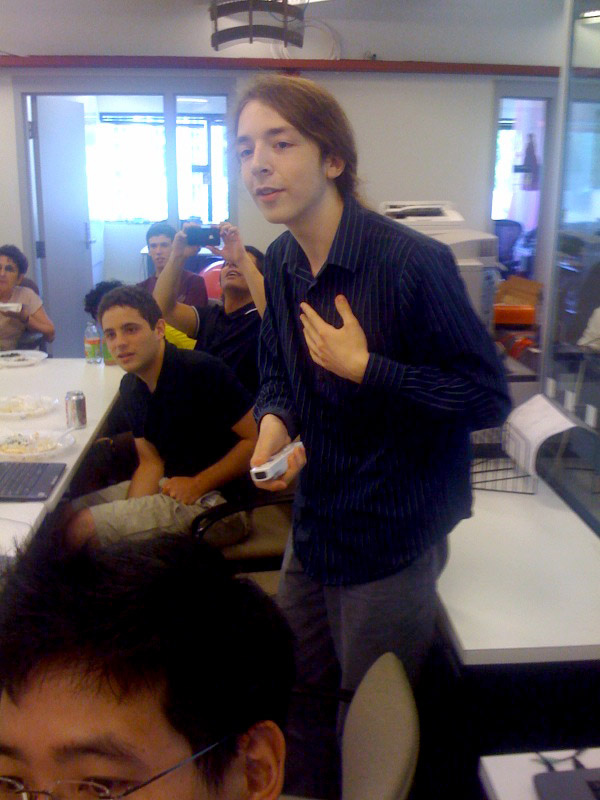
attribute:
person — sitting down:
[120, 205, 215, 328]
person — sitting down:
[5, 528, 305, 794]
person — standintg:
[207, 85, 497, 749]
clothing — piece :
[93, 352, 249, 503]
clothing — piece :
[178, 294, 281, 376]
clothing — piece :
[226, 202, 508, 587]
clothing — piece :
[127, 256, 206, 315]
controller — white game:
[247, 438, 301, 484]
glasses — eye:
[7, 539, 278, 797]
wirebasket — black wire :
[474, 420, 543, 492]